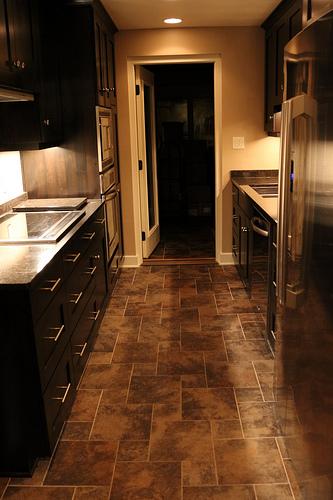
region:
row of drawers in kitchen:
[24, 288, 76, 425]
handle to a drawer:
[44, 323, 66, 342]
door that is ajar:
[132, 65, 174, 264]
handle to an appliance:
[248, 213, 271, 242]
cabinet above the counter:
[8, 7, 68, 147]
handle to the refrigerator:
[274, 89, 310, 312]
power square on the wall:
[226, 135, 254, 152]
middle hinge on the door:
[132, 154, 145, 176]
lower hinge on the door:
[136, 230, 151, 245]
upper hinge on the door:
[128, 82, 146, 99]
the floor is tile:
[132, 277, 209, 346]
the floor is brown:
[131, 450, 239, 496]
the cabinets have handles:
[44, 219, 102, 414]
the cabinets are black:
[10, 306, 36, 452]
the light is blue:
[286, 170, 296, 188]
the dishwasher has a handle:
[245, 215, 268, 234]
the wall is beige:
[228, 71, 253, 110]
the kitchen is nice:
[18, 87, 314, 338]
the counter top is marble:
[8, 246, 54, 271]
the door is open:
[131, 58, 213, 267]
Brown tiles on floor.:
[125, 350, 194, 473]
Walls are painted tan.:
[229, 62, 255, 128]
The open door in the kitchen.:
[137, 68, 163, 258]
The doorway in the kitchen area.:
[130, 63, 217, 255]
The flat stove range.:
[3, 207, 81, 242]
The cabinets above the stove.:
[0, 3, 39, 93]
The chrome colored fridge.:
[267, 40, 331, 481]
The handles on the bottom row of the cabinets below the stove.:
[50, 298, 110, 400]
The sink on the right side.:
[251, 180, 280, 196]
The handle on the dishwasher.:
[249, 209, 267, 234]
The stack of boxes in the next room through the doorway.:
[170, 116, 209, 221]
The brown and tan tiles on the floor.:
[22, 262, 263, 495]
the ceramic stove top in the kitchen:
[0, 210, 84, 242]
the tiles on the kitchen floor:
[0, 263, 307, 499]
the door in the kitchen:
[135, 65, 161, 257]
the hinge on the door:
[134, 83, 140, 95]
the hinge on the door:
[137, 159, 142, 170]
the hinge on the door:
[140, 230, 144, 241]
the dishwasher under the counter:
[246, 202, 270, 342]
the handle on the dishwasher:
[248, 214, 268, 236]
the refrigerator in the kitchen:
[272, 8, 331, 499]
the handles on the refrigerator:
[274, 93, 303, 309]